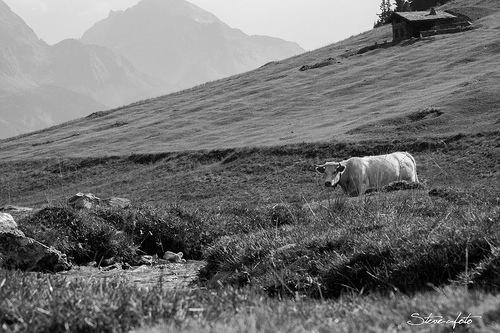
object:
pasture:
[0, 0, 500, 333]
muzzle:
[325, 181, 332, 187]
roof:
[395, 7, 458, 21]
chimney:
[429, 8, 437, 15]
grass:
[0, 0, 500, 333]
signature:
[407, 313, 482, 329]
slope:
[0, 0, 500, 209]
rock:
[0, 192, 187, 272]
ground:
[0, 0, 500, 333]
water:
[70, 260, 206, 290]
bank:
[6, 194, 498, 279]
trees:
[374, 0, 442, 28]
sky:
[3, 0, 398, 82]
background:
[0, 0, 499, 143]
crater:
[376, 110, 444, 127]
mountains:
[0, 0, 306, 140]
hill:
[0, 1, 500, 216]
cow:
[315, 152, 419, 197]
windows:
[395, 29, 399, 38]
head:
[315, 162, 346, 187]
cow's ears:
[337, 165, 345, 172]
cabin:
[383, 7, 458, 42]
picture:
[1, 0, 498, 331]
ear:
[315, 167, 325, 174]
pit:
[375, 111, 445, 127]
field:
[10, 113, 492, 323]